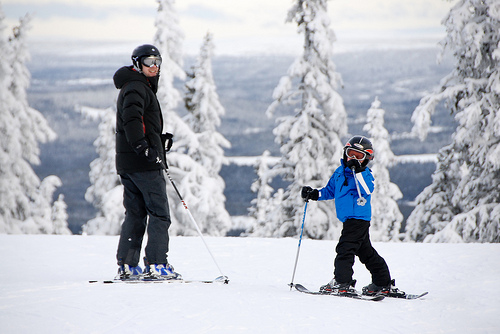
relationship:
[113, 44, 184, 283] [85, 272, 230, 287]
man on skis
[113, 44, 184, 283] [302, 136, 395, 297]
man and boy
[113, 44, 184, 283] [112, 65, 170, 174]
man wearing jacket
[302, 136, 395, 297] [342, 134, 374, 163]
boy has helmet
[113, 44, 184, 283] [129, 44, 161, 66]
man has hat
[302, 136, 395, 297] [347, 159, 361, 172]
boy has hand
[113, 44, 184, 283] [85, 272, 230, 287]
man has skis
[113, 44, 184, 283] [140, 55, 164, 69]
man has goggles